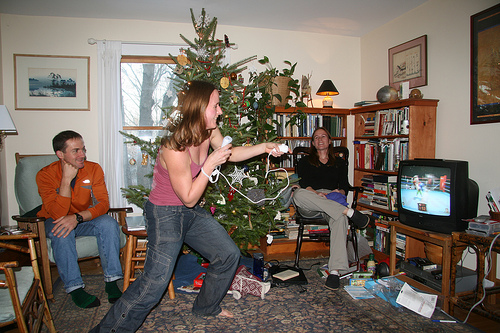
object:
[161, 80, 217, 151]
hair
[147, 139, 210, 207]
shirt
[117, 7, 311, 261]
tree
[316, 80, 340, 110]
lamp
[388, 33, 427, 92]
picture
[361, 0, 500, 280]
wall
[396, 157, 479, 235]
tv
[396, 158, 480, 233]
case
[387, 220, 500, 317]
desk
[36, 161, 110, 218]
shirt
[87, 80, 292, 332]
lady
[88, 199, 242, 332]
jean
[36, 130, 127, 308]
man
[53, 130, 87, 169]
head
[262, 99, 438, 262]
bookcase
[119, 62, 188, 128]
window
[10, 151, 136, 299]
chair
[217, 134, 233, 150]
controller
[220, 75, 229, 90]
ornament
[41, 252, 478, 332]
rug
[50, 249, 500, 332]
ground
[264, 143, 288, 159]
hand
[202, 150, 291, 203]
cord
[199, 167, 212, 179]
strap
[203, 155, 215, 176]
wrist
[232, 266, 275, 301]
present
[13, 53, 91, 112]
frame